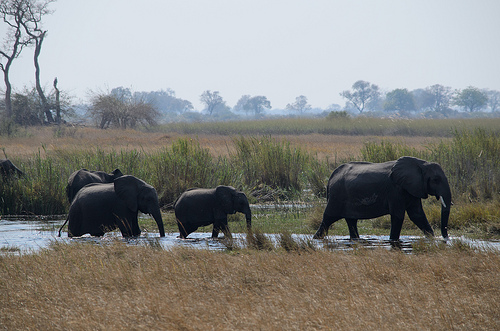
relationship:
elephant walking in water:
[313, 156, 456, 247] [346, 228, 398, 256]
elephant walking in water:
[167, 160, 271, 255] [346, 228, 398, 256]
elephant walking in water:
[54, 172, 170, 242] [346, 228, 398, 256]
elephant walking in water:
[62, 165, 125, 204] [346, 228, 398, 256]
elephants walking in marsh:
[57, 154, 456, 246] [3, 118, 493, 323]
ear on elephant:
[389, 156, 432, 200] [317, 142, 454, 247]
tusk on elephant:
[437, 194, 450, 209] [313, 153, 453, 240]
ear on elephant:
[390, 156, 427, 200] [313, 156, 450, 247]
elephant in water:
[313, 156, 450, 247] [1, 232, 498, 249]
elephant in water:
[313, 156, 456, 247] [1, 210, 499, 262]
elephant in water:
[167, 176, 271, 255] [1, 210, 499, 262]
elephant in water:
[54, 172, 170, 238] [1, 210, 499, 262]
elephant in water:
[62, 165, 125, 204] [1, 210, 499, 262]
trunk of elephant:
[436, 179, 454, 246] [313, 156, 456, 247]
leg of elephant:
[403, 200, 435, 245] [313, 156, 456, 247]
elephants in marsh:
[58, 166, 166, 241] [2, 187, 497, 255]